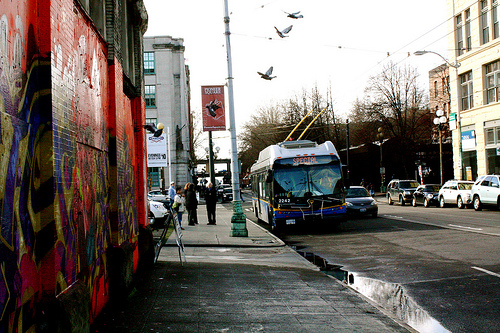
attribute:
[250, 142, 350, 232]
bus — white, blue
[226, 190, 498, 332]
road — concrete, black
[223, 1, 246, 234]
pole — white, metal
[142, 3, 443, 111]
sky — white, bright, blue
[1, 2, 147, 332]
wall — red, yellow, colorful, painted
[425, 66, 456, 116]
building — brown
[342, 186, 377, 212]
car — grey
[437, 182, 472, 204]
car — white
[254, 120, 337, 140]
leaves — green